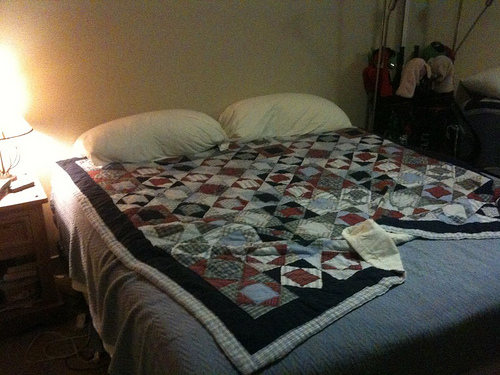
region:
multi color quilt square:
[218, 273, 296, 318]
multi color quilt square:
[261, 256, 338, 303]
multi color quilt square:
[308, 242, 370, 287]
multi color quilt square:
[190, 250, 256, 288]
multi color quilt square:
[234, 236, 299, 274]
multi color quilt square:
[90, 163, 130, 185]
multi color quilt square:
[96, 174, 143, 197]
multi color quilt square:
[104, 185, 156, 209]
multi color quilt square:
[123, 203, 175, 228]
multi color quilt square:
[144, 218, 197, 248]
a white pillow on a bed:
[70, 105, 231, 165]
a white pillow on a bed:
[220, 90, 358, 142]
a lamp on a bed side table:
[2, 63, 35, 194]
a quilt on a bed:
[108, 124, 493, 362]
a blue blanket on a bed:
[71, 230, 174, 370]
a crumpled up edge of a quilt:
[331, 197, 436, 293]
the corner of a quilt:
[217, 306, 287, 373]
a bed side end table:
[5, 188, 64, 325]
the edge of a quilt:
[417, 223, 499, 243]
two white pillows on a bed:
[70, 90, 354, 167]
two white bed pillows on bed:
[77, 81, 367, 168]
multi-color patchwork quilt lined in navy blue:
[55, 114, 497, 373]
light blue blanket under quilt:
[25, 125, 497, 370]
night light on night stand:
[0, 95, 36, 180]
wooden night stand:
[0, 170, 64, 340]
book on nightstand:
[5, 173, 35, 195]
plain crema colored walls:
[5, 0, 499, 241]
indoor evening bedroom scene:
[9, 0, 498, 365]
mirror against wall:
[392, 1, 499, 161]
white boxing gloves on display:
[390, 48, 458, 100]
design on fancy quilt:
[231, 270, 277, 310]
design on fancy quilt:
[273, 257, 325, 294]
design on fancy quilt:
[320, 247, 360, 280]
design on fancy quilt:
[188, 242, 249, 285]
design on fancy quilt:
[237, 258, 283, 283]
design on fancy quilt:
[283, 240, 325, 270]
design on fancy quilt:
[131, 205, 199, 255]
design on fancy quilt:
[116, 185, 155, 210]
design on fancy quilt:
[208, 181, 244, 213]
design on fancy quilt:
[267, 195, 304, 224]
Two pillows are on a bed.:
[73, 84, 358, 169]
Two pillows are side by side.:
[70, 89, 356, 167]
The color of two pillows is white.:
[72, 86, 359, 168]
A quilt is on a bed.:
[52, 123, 498, 373]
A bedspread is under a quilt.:
[52, 150, 498, 374]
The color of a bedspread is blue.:
[47, 150, 498, 374]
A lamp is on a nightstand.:
[0, 50, 35, 206]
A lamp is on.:
[0, 37, 41, 187]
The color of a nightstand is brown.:
[0, 157, 65, 332]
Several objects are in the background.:
[358, 3, 498, 161]